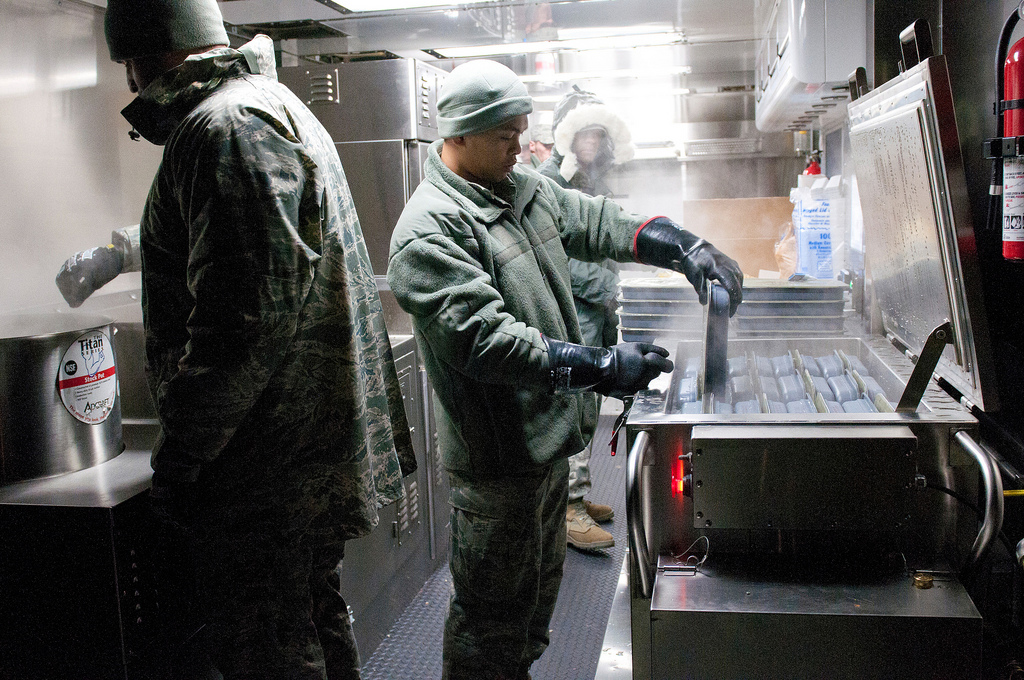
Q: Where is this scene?
A: In a kitchen.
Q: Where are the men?
A: In a kitchen.